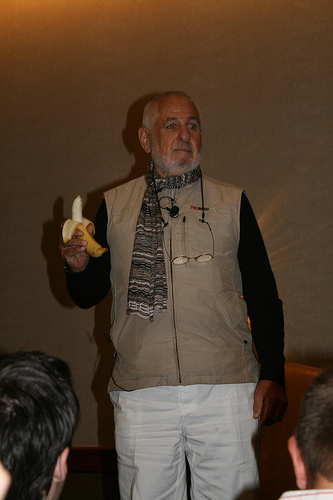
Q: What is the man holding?
A: Banana.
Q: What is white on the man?
A: His pants.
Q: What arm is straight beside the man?
A: His left arm.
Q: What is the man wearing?
A: A brown vest.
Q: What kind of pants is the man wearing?
A: White pants.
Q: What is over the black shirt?
A: A brown vest.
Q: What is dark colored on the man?
A: The black shirt.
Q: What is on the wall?
A: A shadow of the arm and banana.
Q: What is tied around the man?
A: A scarf.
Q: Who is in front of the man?
A: Two men.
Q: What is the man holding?
A: A banana.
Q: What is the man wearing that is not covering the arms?
A: A vest.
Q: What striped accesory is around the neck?
A: A scarf.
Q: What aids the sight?
A: Glasses.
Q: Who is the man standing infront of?
A: Two people.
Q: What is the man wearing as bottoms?
A: Pants.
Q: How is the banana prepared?
A: Peeled.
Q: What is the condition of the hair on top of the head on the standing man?
A: Balding.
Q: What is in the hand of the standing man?
A: A banana.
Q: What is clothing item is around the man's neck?
A: A scarf.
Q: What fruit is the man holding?
A: A banana.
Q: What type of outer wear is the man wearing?
A: A vest.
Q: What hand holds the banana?
A: The right hand.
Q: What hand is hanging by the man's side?
A: The left hand.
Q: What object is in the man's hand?
A: Banana.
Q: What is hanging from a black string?
A: Glasses.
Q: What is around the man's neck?
A: Scarf.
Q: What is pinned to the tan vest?
A: Microphone.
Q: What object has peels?
A: Banana.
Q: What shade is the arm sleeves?
A: Black.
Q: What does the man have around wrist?
A: Watch.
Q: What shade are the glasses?
A: Gold.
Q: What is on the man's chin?
A: Beard.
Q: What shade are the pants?
A: White.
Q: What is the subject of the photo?
A: Man.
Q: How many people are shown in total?
A: Three.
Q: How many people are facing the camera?
A: One.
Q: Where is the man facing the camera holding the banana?
A: Right hand.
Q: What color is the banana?
A: Yellow.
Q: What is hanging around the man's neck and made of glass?
A: Reading glasses.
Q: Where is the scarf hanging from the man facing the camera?
A: Neck.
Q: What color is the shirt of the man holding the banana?
A: Black.